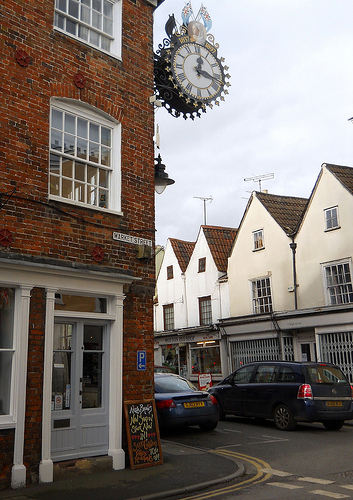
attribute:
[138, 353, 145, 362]
p — parking permitted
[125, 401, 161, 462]
menu — chalkboard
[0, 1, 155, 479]
wall — brick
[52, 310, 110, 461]
door — gray, white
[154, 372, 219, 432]
car — parked, blue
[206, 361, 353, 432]
van — parked, blue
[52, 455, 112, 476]
doorstop — brown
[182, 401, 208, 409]
license plate — black, yellow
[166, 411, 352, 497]
street — gray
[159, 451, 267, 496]
line — yellow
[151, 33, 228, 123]
clock — white, roman numerals, roman numeral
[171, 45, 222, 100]
roman numerals — black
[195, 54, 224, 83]
hands — black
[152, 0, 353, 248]
sky — white, gray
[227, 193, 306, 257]
roofs — brown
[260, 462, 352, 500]
lines — white